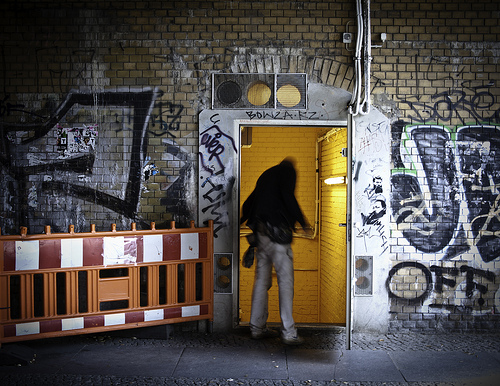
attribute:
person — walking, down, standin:
[241, 156, 318, 346]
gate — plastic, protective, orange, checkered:
[0, 218, 215, 353]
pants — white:
[252, 223, 300, 341]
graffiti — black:
[383, 260, 495, 313]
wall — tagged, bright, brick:
[2, 1, 499, 332]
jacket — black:
[241, 163, 306, 234]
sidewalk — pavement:
[0, 332, 500, 386]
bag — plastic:
[241, 232, 257, 270]